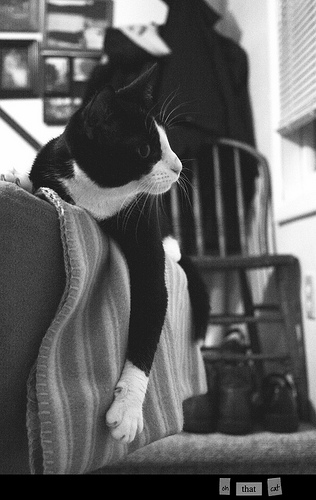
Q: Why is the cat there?
A: Resting.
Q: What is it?
A: A cat.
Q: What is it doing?
A: Hanging her arm.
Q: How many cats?
A: 1.